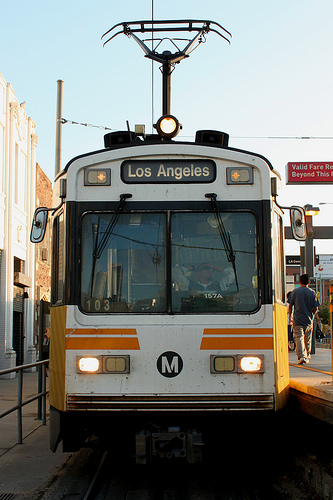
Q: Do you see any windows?
A: Yes, there is a window.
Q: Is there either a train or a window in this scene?
A: Yes, there is a window.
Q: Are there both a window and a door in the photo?
A: No, there is a window but no doors.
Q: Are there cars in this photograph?
A: No, there are no cars.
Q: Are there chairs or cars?
A: No, there are no cars or chairs.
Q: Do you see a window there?
A: Yes, there is a window.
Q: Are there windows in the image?
A: Yes, there is a window.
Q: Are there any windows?
A: Yes, there is a window.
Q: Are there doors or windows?
A: Yes, there is a window.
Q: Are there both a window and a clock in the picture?
A: No, there is a window but no clocks.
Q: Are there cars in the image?
A: No, there are no cars.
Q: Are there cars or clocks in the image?
A: No, there are no cars or clocks.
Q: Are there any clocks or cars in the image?
A: No, there are no cars or clocks.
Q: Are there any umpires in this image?
A: No, there are no umpires.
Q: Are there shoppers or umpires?
A: No, there are no umpires or shoppers.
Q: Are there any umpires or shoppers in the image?
A: No, there are no umpires or shoppers.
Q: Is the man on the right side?
A: Yes, the man is on the right of the image.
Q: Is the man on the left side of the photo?
A: No, the man is on the right of the image.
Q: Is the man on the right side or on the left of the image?
A: The man is on the right of the image.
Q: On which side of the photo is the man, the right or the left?
A: The man is on the right of the image.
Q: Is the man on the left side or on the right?
A: The man is on the right of the image.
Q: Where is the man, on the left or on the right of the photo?
A: The man is on the right of the image.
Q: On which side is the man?
A: The man is on the right of the image.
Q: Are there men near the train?
A: Yes, there is a man near the train.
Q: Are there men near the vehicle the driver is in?
A: Yes, there is a man near the train.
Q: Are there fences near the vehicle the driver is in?
A: No, there is a man near the train.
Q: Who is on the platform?
A: The man is on the platform.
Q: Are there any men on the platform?
A: Yes, there is a man on the platform.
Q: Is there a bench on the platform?
A: No, there is a man on the platform.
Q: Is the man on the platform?
A: Yes, the man is on the platform.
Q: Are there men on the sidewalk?
A: Yes, there is a man on the sidewalk.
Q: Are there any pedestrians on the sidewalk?
A: No, there is a man on the sidewalk.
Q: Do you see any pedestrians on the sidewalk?
A: No, there is a man on the sidewalk.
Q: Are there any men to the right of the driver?
A: Yes, there is a man to the right of the driver.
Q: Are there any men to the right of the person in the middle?
A: Yes, there is a man to the right of the driver.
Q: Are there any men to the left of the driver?
A: No, the man is to the right of the driver.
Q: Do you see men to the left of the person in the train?
A: No, the man is to the right of the driver.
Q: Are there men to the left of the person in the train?
A: No, the man is to the right of the driver.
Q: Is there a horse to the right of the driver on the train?
A: No, there is a man to the right of the driver.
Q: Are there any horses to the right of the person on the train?
A: No, there is a man to the right of the driver.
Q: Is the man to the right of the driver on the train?
A: Yes, the man is to the right of the driver.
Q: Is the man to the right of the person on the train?
A: Yes, the man is to the right of the driver.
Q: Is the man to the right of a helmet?
A: No, the man is to the right of the driver.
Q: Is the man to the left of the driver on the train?
A: No, the man is to the right of the driver.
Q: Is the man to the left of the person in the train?
A: No, the man is to the right of the driver.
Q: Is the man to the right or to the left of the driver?
A: The man is to the right of the driver.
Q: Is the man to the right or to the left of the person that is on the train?
A: The man is to the right of the driver.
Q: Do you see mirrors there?
A: Yes, there is a mirror.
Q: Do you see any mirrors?
A: Yes, there is a mirror.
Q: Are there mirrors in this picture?
A: Yes, there is a mirror.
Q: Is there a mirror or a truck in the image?
A: Yes, there is a mirror.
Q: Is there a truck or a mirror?
A: Yes, there is a mirror.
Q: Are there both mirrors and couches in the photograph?
A: No, there is a mirror but no couches.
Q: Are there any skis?
A: No, there are no skis.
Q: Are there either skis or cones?
A: No, there are no skis or cones.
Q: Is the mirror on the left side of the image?
A: Yes, the mirror is on the left of the image.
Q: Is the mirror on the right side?
A: No, the mirror is on the left of the image.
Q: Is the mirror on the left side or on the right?
A: The mirror is on the left of the image.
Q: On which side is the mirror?
A: The mirror is on the left of the image.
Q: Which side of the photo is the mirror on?
A: The mirror is on the left of the image.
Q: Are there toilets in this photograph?
A: No, there are no toilets.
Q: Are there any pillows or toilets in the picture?
A: No, there are no toilets or pillows.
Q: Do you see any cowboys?
A: No, there are no cowboys.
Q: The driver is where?
A: The driver is on the train.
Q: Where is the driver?
A: The driver is on the train.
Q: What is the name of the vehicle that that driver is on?
A: The vehicle is a train.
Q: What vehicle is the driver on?
A: The driver is on the train.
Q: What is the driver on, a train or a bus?
A: The driver is on a train.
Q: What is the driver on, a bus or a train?
A: The driver is on a train.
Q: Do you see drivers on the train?
A: Yes, there is a driver on the train.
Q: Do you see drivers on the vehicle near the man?
A: Yes, there is a driver on the train.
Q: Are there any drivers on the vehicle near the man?
A: Yes, there is a driver on the train.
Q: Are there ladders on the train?
A: No, there is a driver on the train.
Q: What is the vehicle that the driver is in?
A: The vehicle is a train.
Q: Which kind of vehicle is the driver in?
A: The driver is in the train.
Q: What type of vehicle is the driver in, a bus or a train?
A: The driver is in a train.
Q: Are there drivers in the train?
A: Yes, there is a driver in the train.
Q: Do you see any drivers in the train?
A: Yes, there is a driver in the train.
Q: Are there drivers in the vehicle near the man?
A: Yes, there is a driver in the train.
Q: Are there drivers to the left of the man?
A: Yes, there is a driver to the left of the man.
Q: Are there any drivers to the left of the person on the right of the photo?
A: Yes, there is a driver to the left of the man.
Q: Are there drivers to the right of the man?
A: No, the driver is to the left of the man.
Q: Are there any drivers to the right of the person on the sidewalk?
A: No, the driver is to the left of the man.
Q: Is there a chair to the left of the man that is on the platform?
A: No, there is a driver to the left of the man.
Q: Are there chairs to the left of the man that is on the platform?
A: No, there is a driver to the left of the man.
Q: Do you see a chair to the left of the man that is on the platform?
A: No, there is a driver to the left of the man.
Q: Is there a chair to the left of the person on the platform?
A: No, there is a driver to the left of the man.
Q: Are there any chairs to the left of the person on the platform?
A: No, there is a driver to the left of the man.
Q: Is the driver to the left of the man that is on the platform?
A: Yes, the driver is to the left of the man.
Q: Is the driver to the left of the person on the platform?
A: Yes, the driver is to the left of the man.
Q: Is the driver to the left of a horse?
A: No, the driver is to the left of the man.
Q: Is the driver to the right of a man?
A: No, the driver is to the left of a man.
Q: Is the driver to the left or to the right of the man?
A: The driver is to the left of the man.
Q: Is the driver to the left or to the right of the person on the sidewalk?
A: The driver is to the left of the man.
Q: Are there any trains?
A: Yes, there is a train.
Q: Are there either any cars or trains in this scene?
A: Yes, there is a train.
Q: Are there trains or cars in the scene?
A: Yes, there is a train.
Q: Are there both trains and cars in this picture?
A: No, there is a train but no cars.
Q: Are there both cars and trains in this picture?
A: No, there is a train but no cars.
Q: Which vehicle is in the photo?
A: The vehicle is a train.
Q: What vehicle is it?
A: The vehicle is a train.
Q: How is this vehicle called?
A: This is a train.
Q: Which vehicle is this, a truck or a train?
A: This is a train.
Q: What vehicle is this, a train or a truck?
A: This is a train.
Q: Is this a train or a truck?
A: This is a train.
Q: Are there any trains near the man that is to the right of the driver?
A: Yes, there is a train near the man.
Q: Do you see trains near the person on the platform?
A: Yes, there is a train near the man.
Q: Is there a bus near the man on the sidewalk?
A: No, there is a train near the man.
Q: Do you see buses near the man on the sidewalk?
A: No, there is a train near the man.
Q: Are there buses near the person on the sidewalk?
A: No, there is a train near the man.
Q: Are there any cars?
A: No, there are no cars.